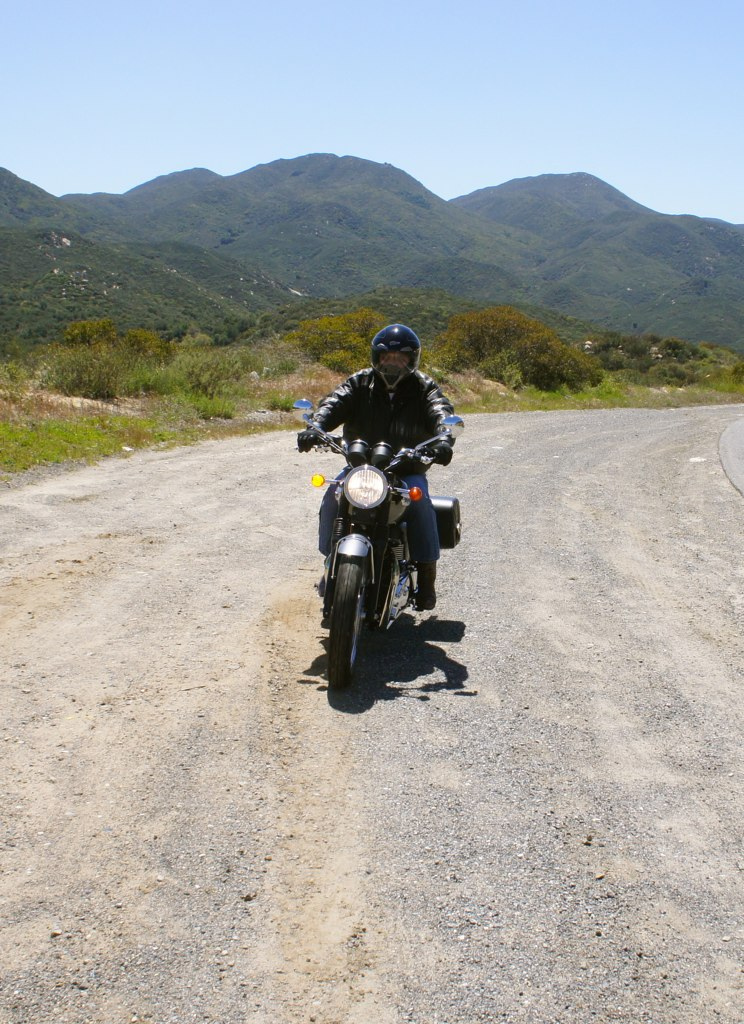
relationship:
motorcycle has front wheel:
[290, 395, 464, 710] [325, 551, 366, 690]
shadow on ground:
[300, 604, 478, 712] [0, 405, 744, 1021]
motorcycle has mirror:
[290, 395, 464, 710] [291, 398, 323, 430]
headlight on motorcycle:
[341, 460, 389, 513] [289, 387, 462, 684]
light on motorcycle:
[408, 485, 421, 499] [290, 395, 464, 710]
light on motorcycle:
[312, 471, 324, 487] [290, 395, 464, 710]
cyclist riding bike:
[295, 318, 456, 613] [290, 391, 464, 689]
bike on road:
[290, 391, 464, 689] [0, 407, 744, 1014]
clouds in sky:
[597, 119, 684, 173] [0, 0, 742, 227]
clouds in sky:
[151, 46, 218, 98] [0, 0, 742, 227]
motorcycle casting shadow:
[290, 395, 464, 710] [300, 604, 478, 712]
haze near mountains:
[2, 157, 741, 224] [0, 164, 742, 357]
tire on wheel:
[327, 556, 362, 704] [350, 583, 363, 669]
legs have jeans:
[319, 466, 439, 589] [397, 474, 440, 561]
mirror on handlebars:
[290, 398, 318, 426] [291, 418, 456, 463]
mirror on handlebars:
[439, 410, 464, 439] [291, 418, 456, 463]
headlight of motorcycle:
[331, 462, 402, 506] [284, 386, 478, 706]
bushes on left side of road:
[2, 300, 741, 466] [9, 411, 721, 1015]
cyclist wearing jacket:
[295, 318, 456, 613] [310, 372, 452, 486]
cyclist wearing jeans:
[295, 318, 456, 613] [314, 461, 435, 604]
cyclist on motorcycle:
[294, 309, 464, 605] [268, 277, 483, 681]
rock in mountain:
[55, 229, 73, 250] [10, 144, 710, 356]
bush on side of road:
[438, 294, 592, 377] [9, 411, 721, 1015]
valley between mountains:
[258, 258, 425, 309] [17, 223, 514, 335]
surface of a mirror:
[434, 409, 469, 440] [439, 411, 466, 441]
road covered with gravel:
[9, 411, 721, 1015] [399, 795, 585, 915]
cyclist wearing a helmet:
[295, 318, 456, 613] [362, 320, 426, 368]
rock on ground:
[239, 890, 259, 906] [14, 151, 721, 1003]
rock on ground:
[340, 938, 373, 978] [14, 151, 721, 1003]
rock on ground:
[577, 829, 602, 847] [14, 151, 721, 1003]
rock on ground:
[62, 971, 83, 999] [14, 151, 721, 1003]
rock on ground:
[273, 722, 295, 746] [14, 151, 721, 1003]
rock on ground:
[654, 964, 678, 986] [14, 151, 721, 1003]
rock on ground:
[515, 734, 544, 754] [14, 151, 721, 1003]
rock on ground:
[274, 742, 302, 767] [14, 151, 721, 1003]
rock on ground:
[449, 965, 474, 998] [14, 151, 721, 1003]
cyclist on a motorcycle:
[295, 318, 456, 613] [290, 395, 464, 710]